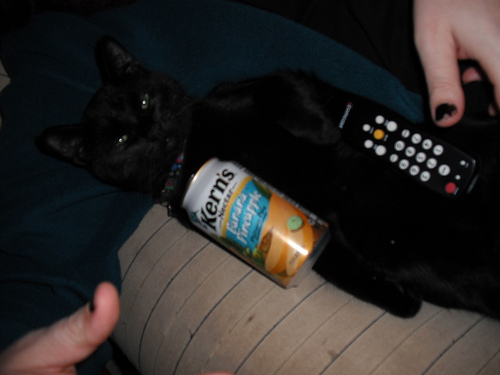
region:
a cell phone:
[281, 65, 490, 210]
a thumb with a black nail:
[47, 253, 115, 349]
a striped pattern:
[148, 237, 303, 367]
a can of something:
[165, 145, 362, 302]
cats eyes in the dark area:
[72, 58, 182, 179]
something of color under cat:
[163, 132, 191, 209]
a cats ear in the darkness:
[35, 120, 98, 170]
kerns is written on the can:
[190, 150, 220, 245]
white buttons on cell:
[375, 110, 475, 184]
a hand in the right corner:
[407, 10, 498, 102]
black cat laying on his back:
[44, 49, 496, 331]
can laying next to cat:
[174, 161, 326, 286]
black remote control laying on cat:
[335, 94, 488, 198]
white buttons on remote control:
[349, 112, 446, 188]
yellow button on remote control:
[369, 127, 388, 141]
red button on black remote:
[443, 179, 458, 195]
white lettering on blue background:
[218, 184, 278, 251]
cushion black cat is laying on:
[53, 84, 497, 373]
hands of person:
[20, 30, 486, 367]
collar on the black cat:
[158, 147, 194, 199]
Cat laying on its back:
[90, 58, 443, 248]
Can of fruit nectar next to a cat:
[181, 157, 343, 279]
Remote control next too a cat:
[346, 99, 480, 201]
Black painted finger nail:
[430, 95, 460, 122]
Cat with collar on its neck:
[152, 161, 185, 209]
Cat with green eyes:
[99, 83, 155, 154]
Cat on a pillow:
[76, 94, 377, 268]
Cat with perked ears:
[30, 53, 167, 155]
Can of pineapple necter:
[183, 171, 336, 284]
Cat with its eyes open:
[111, 73, 164, 163]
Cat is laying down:
[30, 31, 499, 339]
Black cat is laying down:
[25, 28, 497, 333]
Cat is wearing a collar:
[157, 137, 188, 214]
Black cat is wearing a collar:
[155, 137, 195, 217]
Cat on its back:
[36, 37, 496, 327]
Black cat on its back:
[42, 30, 499, 333]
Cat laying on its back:
[32, 27, 499, 324]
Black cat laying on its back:
[35, 32, 497, 327]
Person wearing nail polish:
[84, 91, 466, 315]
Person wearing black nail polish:
[84, 99, 462, 318]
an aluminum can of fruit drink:
[187, 159, 327, 281]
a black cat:
[42, 45, 499, 307]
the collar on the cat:
[160, 146, 188, 206]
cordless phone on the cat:
[334, 95, 481, 200]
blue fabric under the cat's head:
[4, 6, 416, 373]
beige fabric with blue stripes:
[106, 207, 491, 373]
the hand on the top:
[414, 6, 499, 125]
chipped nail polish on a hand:
[435, 102, 455, 122]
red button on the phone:
[444, 182, 457, 192]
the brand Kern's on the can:
[196, 165, 236, 232]